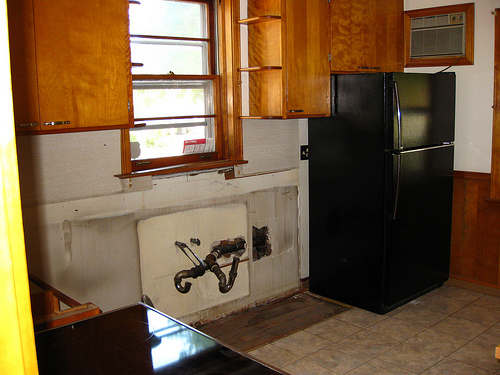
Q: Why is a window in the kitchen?
A: To let light in.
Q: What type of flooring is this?
A: It is tile.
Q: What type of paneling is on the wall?
A: The type is wood paneling.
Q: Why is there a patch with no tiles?
A: Use to be a sink.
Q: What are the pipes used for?
A: The pipes are used for a sink.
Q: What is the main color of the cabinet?
A: Brown.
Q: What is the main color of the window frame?
A: Brown.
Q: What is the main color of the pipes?
A: Gray.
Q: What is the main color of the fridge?
A: Black.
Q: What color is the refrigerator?
A: Black.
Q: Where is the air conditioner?
A: Above the refrigerator.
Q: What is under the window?
A: Pipes.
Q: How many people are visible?
A: Zero.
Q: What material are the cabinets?
A: Wood.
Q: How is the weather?
A: Sunny.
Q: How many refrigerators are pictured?
A: 1.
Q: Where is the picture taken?
A: Kitchen.